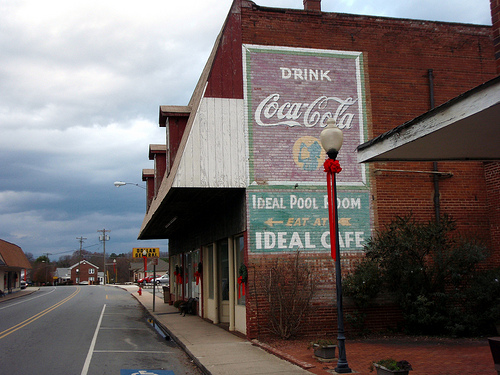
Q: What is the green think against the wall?
A: Bush.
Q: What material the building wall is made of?
A: Brick.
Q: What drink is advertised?
A: Coca Cola.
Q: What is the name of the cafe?
A: Ideal Cafe.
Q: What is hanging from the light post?
A: A red bow and ribbon.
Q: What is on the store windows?
A: Wreaths.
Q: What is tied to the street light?
A: A red bow.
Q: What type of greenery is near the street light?
A: A bush.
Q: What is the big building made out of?
A: Red brick.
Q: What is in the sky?
A: Clouds.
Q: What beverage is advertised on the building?
A: Coca Cola.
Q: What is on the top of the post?
A: A lamp.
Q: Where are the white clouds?
A: In the sky.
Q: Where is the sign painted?
A: On the brick wall.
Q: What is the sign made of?
A: Paint.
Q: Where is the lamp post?
A: Front right.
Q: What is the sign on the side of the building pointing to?
A: Ideal Cafe.